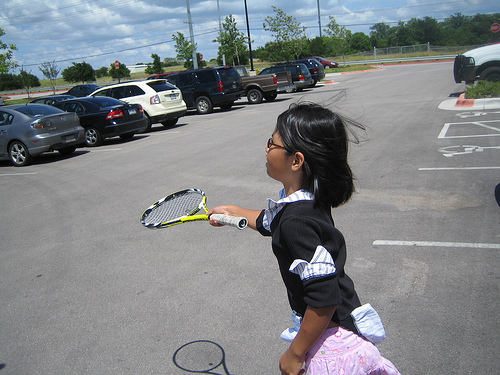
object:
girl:
[208, 90, 401, 375]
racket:
[140, 186, 249, 231]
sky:
[0, 0, 500, 79]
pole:
[316, 0, 321, 38]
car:
[0, 102, 84, 167]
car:
[49, 95, 148, 147]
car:
[86, 78, 187, 133]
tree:
[0, 27, 20, 78]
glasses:
[267, 138, 289, 152]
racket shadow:
[172, 338, 230, 374]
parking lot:
[0, 61, 500, 373]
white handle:
[209, 213, 248, 230]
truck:
[233, 65, 297, 105]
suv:
[164, 65, 246, 115]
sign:
[115, 60, 120, 70]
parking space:
[417, 144, 498, 171]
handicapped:
[437, 144, 499, 156]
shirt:
[254, 187, 386, 345]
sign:
[196, 53, 203, 66]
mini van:
[257, 63, 314, 93]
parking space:
[454, 111, 499, 118]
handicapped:
[455, 111, 487, 119]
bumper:
[293, 79, 314, 87]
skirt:
[299, 326, 401, 374]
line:
[418, 167, 499, 171]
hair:
[276, 89, 365, 210]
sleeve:
[255, 186, 387, 344]